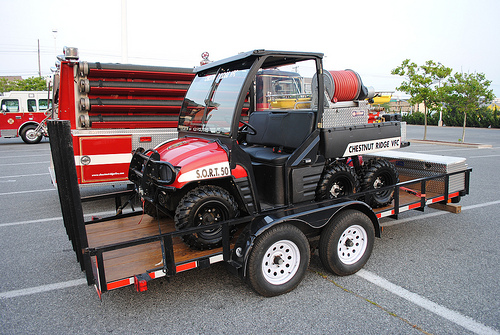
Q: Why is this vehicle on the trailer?
A: Transporting.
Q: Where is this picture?
A: Parking lot.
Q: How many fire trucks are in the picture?
A: Two.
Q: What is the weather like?
A: Sunny.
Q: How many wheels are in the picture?
A: Six.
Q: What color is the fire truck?
A: Red.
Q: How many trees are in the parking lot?
A: Two.